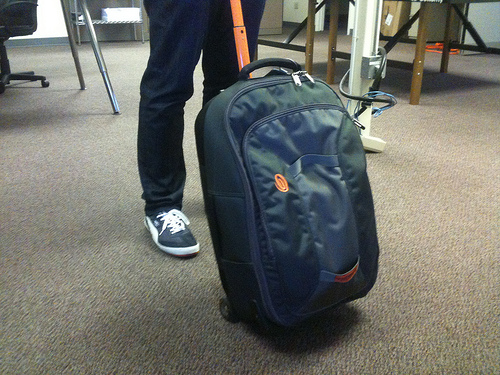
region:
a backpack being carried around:
[191, 62, 386, 334]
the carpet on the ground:
[6, 40, 499, 374]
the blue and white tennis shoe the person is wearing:
[143, 211, 200, 258]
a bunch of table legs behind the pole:
[297, 4, 436, 113]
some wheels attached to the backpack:
[210, 294, 235, 323]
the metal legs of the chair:
[63, 5, 129, 113]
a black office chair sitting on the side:
[3, 2, 52, 94]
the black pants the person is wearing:
[131, 1, 261, 221]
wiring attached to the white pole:
[336, 49, 396, 129]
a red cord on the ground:
[423, 36, 461, 56]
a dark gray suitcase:
[194, 58, 395, 346]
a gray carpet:
[0, 27, 498, 372]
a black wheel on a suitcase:
[210, 297, 237, 320]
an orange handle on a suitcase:
[222, 0, 259, 80]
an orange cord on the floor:
[425, 32, 465, 57]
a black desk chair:
[0, 1, 56, 92]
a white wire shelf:
[68, 1, 152, 45]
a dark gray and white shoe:
[130, 202, 214, 272]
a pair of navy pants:
[135, 0, 269, 218]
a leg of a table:
[400, 1, 437, 110]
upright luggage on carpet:
[186, 46, 388, 341]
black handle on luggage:
[232, 47, 311, 90]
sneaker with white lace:
[140, 200, 203, 269]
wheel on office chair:
[14, 61, 57, 100]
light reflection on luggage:
[306, 99, 348, 141]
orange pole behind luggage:
[219, 11, 257, 83]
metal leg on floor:
[87, 23, 130, 127]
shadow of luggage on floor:
[262, 306, 366, 361]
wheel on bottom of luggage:
[207, 292, 239, 327]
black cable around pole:
[337, 47, 403, 116]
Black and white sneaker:
[143, 204, 203, 258]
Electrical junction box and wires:
[339, 50, 395, 122]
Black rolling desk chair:
[0, 0, 50, 92]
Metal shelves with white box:
[65, 1, 147, 43]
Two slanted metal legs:
[56, 0, 129, 117]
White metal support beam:
[345, 0, 383, 142]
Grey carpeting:
[8, 243, 93, 370]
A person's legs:
[138, 0, 268, 256]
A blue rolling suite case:
[198, 0, 379, 330]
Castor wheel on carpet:
[208, 294, 238, 322]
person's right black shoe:
[132, 202, 205, 260]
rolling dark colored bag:
[183, 54, 391, 340]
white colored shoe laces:
[156, 204, 189, 237]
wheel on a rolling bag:
[212, 295, 238, 324]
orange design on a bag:
[271, 165, 291, 200]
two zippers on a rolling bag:
[289, 65, 315, 93]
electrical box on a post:
[359, 50, 389, 83]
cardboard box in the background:
[378, 0, 415, 43]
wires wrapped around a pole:
[336, 35, 405, 134]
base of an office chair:
[1, 67, 51, 91]